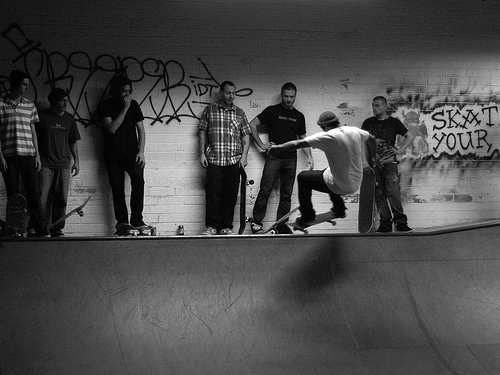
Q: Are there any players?
A: No, there are no players.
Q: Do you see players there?
A: No, there are no players.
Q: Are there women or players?
A: No, there are no players or women.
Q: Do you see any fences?
A: No, there are no fences.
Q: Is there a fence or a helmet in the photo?
A: No, there are no fences or helmets.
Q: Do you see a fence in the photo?
A: No, there are no fences.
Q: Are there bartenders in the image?
A: No, there are no bartenders.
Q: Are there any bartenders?
A: No, there are no bartenders.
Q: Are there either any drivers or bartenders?
A: No, there are no bartenders or drivers.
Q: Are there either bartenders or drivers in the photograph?
A: No, there are no bartenders or drivers.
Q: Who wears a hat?
A: The man wears a hat.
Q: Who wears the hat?
A: The man wears a hat.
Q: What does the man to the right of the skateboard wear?
A: The man wears a hat.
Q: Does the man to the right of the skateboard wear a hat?
A: Yes, the man wears a hat.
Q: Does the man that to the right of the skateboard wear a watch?
A: No, the man wears a hat.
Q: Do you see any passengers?
A: No, there are no passengers.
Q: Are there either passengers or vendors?
A: No, there are no passengers or vendors.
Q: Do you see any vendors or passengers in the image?
A: No, there are no passengers or vendors.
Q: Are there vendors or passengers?
A: No, there are no passengers or vendors.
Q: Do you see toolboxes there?
A: No, there are no toolboxes.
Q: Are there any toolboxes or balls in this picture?
A: No, there are no toolboxes or balls.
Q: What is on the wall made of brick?
A: The graffiti is on the wall.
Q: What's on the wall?
A: The graffiti is on the wall.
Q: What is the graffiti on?
A: The graffiti is on the wall.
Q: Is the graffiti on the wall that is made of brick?
A: Yes, the graffiti is on the wall.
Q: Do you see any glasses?
A: No, there are no glasses.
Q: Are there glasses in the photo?
A: No, there are no glasses.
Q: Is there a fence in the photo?
A: No, there are no fences.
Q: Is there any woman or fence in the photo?
A: No, there are no fences or women.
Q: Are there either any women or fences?
A: No, there are no fences or women.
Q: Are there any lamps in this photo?
A: No, there are no lamps.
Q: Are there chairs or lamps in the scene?
A: No, there are no lamps or chairs.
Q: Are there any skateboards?
A: Yes, there is a skateboard.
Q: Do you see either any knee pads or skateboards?
A: Yes, there is a skateboard.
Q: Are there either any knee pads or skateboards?
A: Yes, there is a skateboard.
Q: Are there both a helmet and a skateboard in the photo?
A: No, there is a skateboard but no helmets.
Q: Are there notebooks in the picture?
A: No, there are no notebooks.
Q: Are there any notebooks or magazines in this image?
A: No, there are no notebooks or magazines.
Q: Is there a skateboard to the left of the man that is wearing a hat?
A: Yes, there is a skateboard to the left of the man.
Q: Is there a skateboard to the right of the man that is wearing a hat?
A: No, the skateboard is to the left of the man.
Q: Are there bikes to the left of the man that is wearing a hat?
A: No, there is a skateboard to the left of the man.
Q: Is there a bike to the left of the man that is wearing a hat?
A: No, there is a skateboard to the left of the man.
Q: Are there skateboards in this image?
A: Yes, there is a skateboard.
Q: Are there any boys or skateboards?
A: Yes, there is a skateboard.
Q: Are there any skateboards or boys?
A: Yes, there is a skateboard.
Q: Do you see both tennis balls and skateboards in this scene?
A: No, there is a skateboard but no tennis balls.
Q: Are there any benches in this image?
A: No, there are no benches.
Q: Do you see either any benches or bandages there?
A: No, there are no benches or bandages.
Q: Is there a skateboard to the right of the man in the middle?
A: Yes, there is a skateboard to the right of the man.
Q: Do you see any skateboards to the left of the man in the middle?
A: No, the skateboard is to the right of the man.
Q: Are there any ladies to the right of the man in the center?
A: No, there is a skateboard to the right of the man.